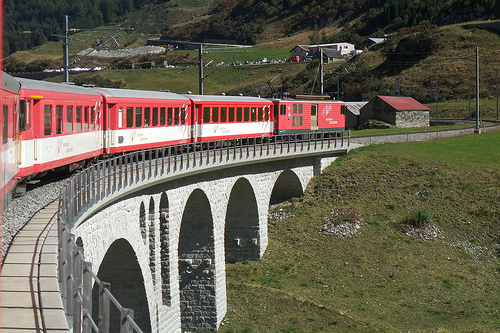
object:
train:
[0, 69, 346, 223]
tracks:
[1, 111, 477, 267]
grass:
[25, 36, 497, 332]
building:
[359, 95, 431, 128]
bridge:
[61, 130, 351, 332]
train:
[173, 90, 209, 138]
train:
[181, 91, 230, 152]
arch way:
[177, 187, 216, 333]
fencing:
[56, 221, 134, 314]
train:
[223, 94, 283, 150]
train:
[188, 98, 288, 147]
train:
[105, 87, 222, 166]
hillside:
[311, 183, 394, 330]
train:
[102, 87, 200, 163]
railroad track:
[213, 135, 243, 168]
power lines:
[243, 40, 266, 108]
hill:
[344, 161, 390, 257]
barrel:
[295, 56, 302, 62]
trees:
[3, 0, 152, 53]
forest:
[4, 0, 146, 51]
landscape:
[272, 199, 498, 259]